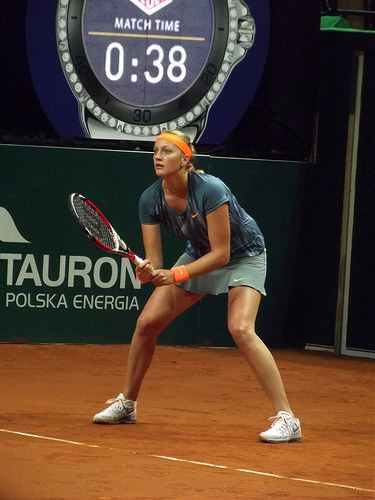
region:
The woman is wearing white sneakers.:
[63, 375, 318, 441]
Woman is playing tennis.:
[48, 139, 314, 409]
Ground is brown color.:
[160, 366, 246, 445]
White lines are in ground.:
[30, 415, 246, 483]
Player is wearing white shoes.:
[75, 384, 312, 462]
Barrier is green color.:
[10, 165, 326, 330]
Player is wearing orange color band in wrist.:
[165, 257, 181, 282]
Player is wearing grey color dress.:
[129, 189, 294, 329]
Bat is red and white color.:
[60, 182, 145, 269]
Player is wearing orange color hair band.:
[153, 117, 213, 184]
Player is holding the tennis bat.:
[51, 132, 314, 438]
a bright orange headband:
[147, 132, 202, 164]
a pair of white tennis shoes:
[72, 372, 321, 451]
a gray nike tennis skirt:
[132, 235, 299, 310]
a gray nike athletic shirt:
[124, 174, 284, 268]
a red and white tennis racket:
[35, 172, 164, 295]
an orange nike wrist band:
[164, 259, 200, 297]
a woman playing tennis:
[41, 102, 316, 495]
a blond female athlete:
[60, 114, 338, 480]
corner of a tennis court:
[6, 327, 369, 496]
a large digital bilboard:
[22, 0, 324, 184]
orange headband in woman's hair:
[151, 123, 209, 160]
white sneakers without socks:
[90, 390, 325, 460]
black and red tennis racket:
[68, 189, 145, 279]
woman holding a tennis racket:
[76, 131, 264, 314]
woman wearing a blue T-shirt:
[134, 180, 258, 250]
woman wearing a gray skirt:
[199, 251, 277, 296]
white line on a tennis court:
[29, 425, 244, 498]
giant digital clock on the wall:
[51, 2, 253, 117]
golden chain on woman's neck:
[160, 180, 195, 197]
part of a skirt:
[241, 271, 271, 286]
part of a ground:
[134, 453, 168, 481]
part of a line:
[166, 448, 193, 477]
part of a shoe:
[264, 423, 297, 444]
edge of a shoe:
[247, 419, 289, 450]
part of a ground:
[186, 470, 217, 482]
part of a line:
[179, 436, 213, 477]